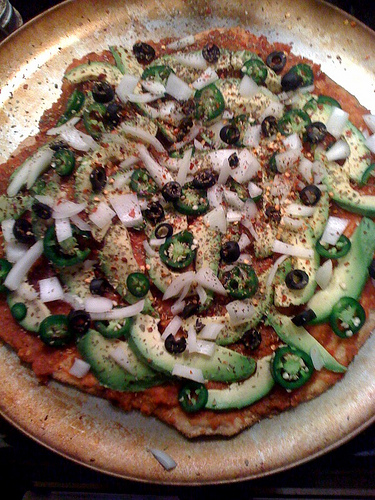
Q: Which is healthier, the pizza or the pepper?
A: The pepper is healthier than the pizza.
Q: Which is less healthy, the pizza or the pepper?
A: The pizza is less healthy than the pepper.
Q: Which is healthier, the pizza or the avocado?
A: The avocado is healthier than the pizza.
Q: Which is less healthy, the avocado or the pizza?
A: The pizza is less healthy than the avocado.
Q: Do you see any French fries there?
A: No, there are no French fries.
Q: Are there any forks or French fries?
A: No, there are no French fries or forks.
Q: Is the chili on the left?
A: Yes, the chili is on the left of the image.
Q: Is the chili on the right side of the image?
A: No, the chili is on the left of the image.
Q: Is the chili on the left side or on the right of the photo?
A: The chili is on the left of the image.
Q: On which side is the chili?
A: The chili is on the left of the image.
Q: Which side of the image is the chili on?
A: The chili is on the left of the image.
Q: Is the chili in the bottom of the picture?
A: Yes, the chili is in the bottom of the image.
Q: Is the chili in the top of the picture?
A: No, the chili is in the bottom of the image.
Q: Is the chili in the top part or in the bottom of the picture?
A: The chili is in the bottom of the image.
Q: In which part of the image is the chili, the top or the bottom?
A: The chili is in the bottom of the image.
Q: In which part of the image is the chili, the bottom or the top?
A: The chili is in the bottom of the image.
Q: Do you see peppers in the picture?
A: Yes, there is a pepper.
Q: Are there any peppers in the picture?
A: Yes, there is a pepper.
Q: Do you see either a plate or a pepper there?
A: Yes, there is a pepper.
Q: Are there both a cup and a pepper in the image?
A: No, there is a pepper but no cups.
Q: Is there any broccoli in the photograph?
A: No, there is no broccoli.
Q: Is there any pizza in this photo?
A: Yes, there is a pizza.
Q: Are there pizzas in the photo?
A: Yes, there is a pizza.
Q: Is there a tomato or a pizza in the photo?
A: Yes, there is a pizza.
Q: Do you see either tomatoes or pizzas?
A: Yes, there is a pizza.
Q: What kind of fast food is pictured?
A: The fast food is a pizza.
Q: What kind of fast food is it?
A: The food is a pizza.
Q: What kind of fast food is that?
A: This is a pizza.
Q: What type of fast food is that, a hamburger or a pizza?
A: This is a pizza.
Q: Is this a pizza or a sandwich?
A: This is a pizza.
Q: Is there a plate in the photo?
A: Yes, there is a plate.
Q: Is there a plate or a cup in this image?
A: Yes, there is a plate.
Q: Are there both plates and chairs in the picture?
A: No, there is a plate but no chairs.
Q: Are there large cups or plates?
A: Yes, there is a large plate.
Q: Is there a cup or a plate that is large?
A: Yes, the plate is large.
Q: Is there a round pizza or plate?
A: Yes, there is a round plate.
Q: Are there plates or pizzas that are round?
A: Yes, the plate is round.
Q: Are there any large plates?
A: Yes, there is a large plate.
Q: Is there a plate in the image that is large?
A: Yes, there is a plate that is large.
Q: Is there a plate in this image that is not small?
A: Yes, there is a large plate.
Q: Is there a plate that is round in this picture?
A: Yes, there is a round plate.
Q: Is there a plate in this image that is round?
A: Yes, there is a plate that is round.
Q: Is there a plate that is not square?
A: Yes, there is a round plate.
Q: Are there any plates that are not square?
A: Yes, there is a round plate.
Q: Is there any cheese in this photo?
A: No, there is no cheese.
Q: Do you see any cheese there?
A: No, there is no cheese.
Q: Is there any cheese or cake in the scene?
A: No, there are no cheese or cakes.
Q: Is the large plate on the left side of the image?
A: Yes, the plate is on the left of the image.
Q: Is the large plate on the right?
A: No, the plate is on the left of the image.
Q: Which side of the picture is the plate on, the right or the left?
A: The plate is on the left of the image.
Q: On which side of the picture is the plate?
A: The plate is on the left of the image.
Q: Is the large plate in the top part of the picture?
A: Yes, the plate is in the top of the image.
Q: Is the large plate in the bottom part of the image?
A: No, the plate is in the top of the image.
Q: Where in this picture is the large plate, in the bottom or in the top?
A: The plate is in the top of the image.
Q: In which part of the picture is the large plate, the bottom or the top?
A: The plate is in the top of the image.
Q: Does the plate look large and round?
A: Yes, the plate is large and round.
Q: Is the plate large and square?
A: No, the plate is large but round.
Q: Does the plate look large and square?
A: No, the plate is large but round.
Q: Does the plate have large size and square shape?
A: No, the plate is large but round.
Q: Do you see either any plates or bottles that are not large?
A: No, there is a plate but it is large.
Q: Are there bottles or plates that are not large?
A: No, there is a plate but it is large.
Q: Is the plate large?
A: Yes, the plate is large.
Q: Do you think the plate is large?
A: Yes, the plate is large.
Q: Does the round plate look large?
A: Yes, the plate is large.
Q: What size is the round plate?
A: The plate is large.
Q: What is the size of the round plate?
A: The plate is large.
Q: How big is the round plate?
A: The plate is large.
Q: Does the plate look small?
A: No, the plate is large.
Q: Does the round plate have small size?
A: No, the plate is large.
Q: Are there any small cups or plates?
A: No, there is a plate but it is large.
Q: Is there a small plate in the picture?
A: No, there is a plate but it is large.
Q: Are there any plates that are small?
A: No, there is a plate but it is large.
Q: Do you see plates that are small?
A: No, there is a plate but it is large.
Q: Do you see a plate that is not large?
A: No, there is a plate but it is large.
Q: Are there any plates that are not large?
A: No, there is a plate but it is large.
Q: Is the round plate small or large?
A: The plate is large.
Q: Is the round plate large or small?
A: The plate is large.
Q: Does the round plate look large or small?
A: The plate is large.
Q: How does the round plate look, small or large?
A: The plate is large.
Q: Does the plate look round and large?
A: Yes, the plate is round and large.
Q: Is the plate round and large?
A: Yes, the plate is round and large.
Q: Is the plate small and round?
A: No, the plate is round but large.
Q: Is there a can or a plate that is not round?
A: No, there is a plate but it is round.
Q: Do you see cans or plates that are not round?
A: No, there is a plate but it is round.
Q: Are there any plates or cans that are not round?
A: No, there is a plate but it is round.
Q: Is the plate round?
A: Yes, the plate is round.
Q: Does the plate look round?
A: Yes, the plate is round.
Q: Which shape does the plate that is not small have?
A: The plate has round shape.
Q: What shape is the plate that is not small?
A: The plate is round.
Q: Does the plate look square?
A: No, the plate is round.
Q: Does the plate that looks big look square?
A: No, the plate is round.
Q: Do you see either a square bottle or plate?
A: No, there is a plate but it is round.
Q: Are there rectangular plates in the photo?
A: No, there is a plate but it is round.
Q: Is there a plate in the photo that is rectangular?
A: No, there is a plate but it is round.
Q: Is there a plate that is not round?
A: No, there is a plate but it is round.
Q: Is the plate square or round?
A: The plate is round.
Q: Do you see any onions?
A: Yes, there is an onion.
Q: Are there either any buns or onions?
A: Yes, there is an onion.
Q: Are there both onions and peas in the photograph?
A: No, there is an onion but no peas.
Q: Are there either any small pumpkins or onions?
A: Yes, there is a small onion.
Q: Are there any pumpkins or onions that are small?
A: Yes, the onion is small.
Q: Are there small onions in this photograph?
A: Yes, there is a small onion.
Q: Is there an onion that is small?
A: Yes, there is an onion that is small.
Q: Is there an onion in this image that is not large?
A: Yes, there is a small onion.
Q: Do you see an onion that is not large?
A: Yes, there is a small onion.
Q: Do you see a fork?
A: No, there are no forks.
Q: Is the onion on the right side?
A: Yes, the onion is on the right of the image.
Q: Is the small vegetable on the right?
A: Yes, the onion is on the right of the image.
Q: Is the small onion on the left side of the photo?
A: No, the onion is on the right of the image.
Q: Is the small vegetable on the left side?
A: No, the onion is on the right of the image.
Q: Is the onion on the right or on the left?
A: The onion is on the right of the image.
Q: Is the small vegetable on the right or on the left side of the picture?
A: The onion is on the right of the image.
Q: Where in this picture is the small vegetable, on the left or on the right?
A: The onion is on the right of the image.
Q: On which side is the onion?
A: The onion is on the right of the image.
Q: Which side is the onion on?
A: The onion is on the right of the image.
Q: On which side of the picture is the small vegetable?
A: The onion is on the right of the image.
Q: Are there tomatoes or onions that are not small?
A: No, there is an onion but it is small.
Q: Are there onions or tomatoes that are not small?
A: No, there is an onion but it is small.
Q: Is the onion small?
A: Yes, the onion is small.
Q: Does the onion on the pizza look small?
A: Yes, the onion is small.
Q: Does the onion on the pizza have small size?
A: Yes, the onion is small.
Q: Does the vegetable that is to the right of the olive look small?
A: Yes, the onion is small.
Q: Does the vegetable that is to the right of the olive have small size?
A: Yes, the onion is small.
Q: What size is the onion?
A: The onion is small.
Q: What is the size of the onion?
A: The onion is small.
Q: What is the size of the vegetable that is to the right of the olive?
A: The onion is small.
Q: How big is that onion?
A: The onion is small.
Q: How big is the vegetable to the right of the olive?
A: The onion is small.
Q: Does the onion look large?
A: No, the onion is small.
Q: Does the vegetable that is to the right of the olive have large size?
A: No, the onion is small.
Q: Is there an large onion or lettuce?
A: No, there is an onion but it is small.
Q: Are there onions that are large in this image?
A: No, there is an onion but it is small.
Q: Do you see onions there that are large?
A: No, there is an onion but it is small.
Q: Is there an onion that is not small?
A: No, there is an onion but it is small.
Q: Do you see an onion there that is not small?
A: No, there is an onion but it is small.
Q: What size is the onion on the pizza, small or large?
A: The onion is small.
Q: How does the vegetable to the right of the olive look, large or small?
A: The onion is small.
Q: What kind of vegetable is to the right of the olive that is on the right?
A: The vegetable is an onion.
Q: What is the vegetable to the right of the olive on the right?
A: The vegetable is an onion.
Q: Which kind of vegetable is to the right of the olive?
A: The vegetable is an onion.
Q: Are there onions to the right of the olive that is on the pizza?
A: Yes, there is an onion to the right of the olive.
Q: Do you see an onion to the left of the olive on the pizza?
A: No, the onion is to the right of the olive.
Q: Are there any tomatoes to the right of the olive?
A: No, there is an onion to the right of the olive.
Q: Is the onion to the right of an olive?
A: Yes, the onion is to the right of an olive.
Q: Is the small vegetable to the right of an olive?
A: Yes, the onion is to the right of an olive.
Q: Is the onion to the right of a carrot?
A: No, the onion is to the right of an olive.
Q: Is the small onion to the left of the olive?
A: No, the onion is to the right of the olive.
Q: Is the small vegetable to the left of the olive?
A: No, the onion is to the right of the olive.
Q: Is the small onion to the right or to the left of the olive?
A: The onion is to the right of the olive.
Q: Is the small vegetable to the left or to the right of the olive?
A: The onion is to the right of the olive.